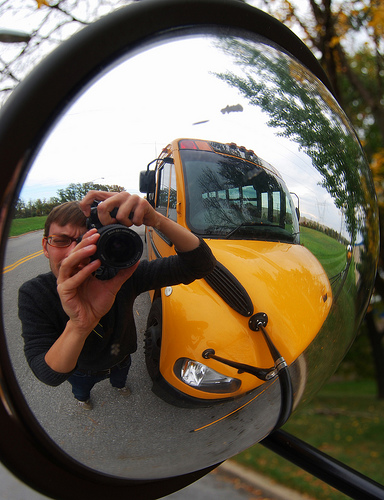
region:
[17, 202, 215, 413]
reflection of a man in a mirror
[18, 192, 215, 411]
a man taking a picture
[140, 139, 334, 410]
a big yellow school bus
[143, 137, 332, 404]
reflection of a school bus in a mirror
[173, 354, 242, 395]
right headlight of a yellow bus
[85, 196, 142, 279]
a man's camera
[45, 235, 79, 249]
glasses on a man's face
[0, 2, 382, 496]
mirror of a yellow school bus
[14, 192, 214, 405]
man taking picture of a mirror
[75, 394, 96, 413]
reflection of a man's right foot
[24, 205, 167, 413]
reflection of a man taking a photo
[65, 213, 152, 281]
the camera lens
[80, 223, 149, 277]
the camera lens is black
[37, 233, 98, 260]
the man wears glasses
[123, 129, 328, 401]
reflection of a yellow school bus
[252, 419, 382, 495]
the arm supporting the mirror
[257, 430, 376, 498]
the arm is black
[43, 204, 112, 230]
the man has brown hair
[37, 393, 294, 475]
reflection of road in the mirror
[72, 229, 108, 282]
the man's fingers holding the camera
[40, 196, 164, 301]
Man looking into the camera.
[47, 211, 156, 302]
Man has a camera by his face.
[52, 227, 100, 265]
Man is wearing glasses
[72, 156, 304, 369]
Man next to the school bus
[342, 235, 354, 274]
Person in the green grass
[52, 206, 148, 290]
The man is focusing the camera.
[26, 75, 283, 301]
Man is taking picture of the side view mirror.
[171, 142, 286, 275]
the bus is yellow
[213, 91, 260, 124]
An object in the sky.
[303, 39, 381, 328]
The bus is parked next to the tree.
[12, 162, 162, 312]
man holding a camera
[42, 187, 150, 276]
man with glasses and a camera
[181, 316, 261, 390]
yellow vehicle with light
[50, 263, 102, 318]
hand of man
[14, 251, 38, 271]
double yellow line on street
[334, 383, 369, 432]
green grass next to bus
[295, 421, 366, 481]
black pole on bus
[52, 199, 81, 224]
brown hair on man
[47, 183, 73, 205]
trees in the background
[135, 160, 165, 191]
rear view mirror on bus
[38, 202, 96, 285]
the head of a man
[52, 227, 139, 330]
the hand of a man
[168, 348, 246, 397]
a headlight of a bus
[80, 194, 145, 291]
a black camera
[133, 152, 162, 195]
a side view mirror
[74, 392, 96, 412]
a brown shoe on the man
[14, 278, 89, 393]
the arm of the man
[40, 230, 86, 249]
a pair of brown glasses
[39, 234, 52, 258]
the ear of the man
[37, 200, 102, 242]
the brown hair of the man